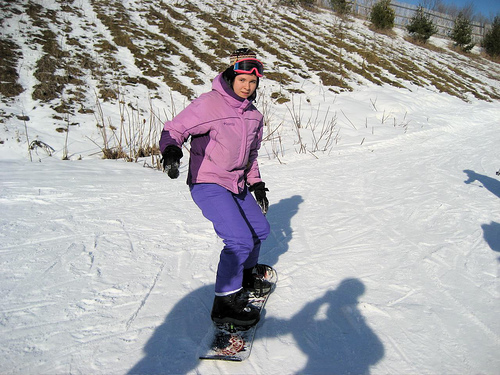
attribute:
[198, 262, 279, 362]
snowboard — small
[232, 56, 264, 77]
goggles — pink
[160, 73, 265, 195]
coat — pink, purple, lavender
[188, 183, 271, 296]
snow pants — purple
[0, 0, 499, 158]
slope — grassy, snow-covered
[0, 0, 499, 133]
snow — patchy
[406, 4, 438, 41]
tree — small, green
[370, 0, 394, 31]
tree — small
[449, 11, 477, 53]
tree — small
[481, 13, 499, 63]
tree — small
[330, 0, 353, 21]
tree — small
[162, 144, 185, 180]
glove — black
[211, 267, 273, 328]
snow boots — black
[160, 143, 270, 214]
gloves — black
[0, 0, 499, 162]
grass — brown